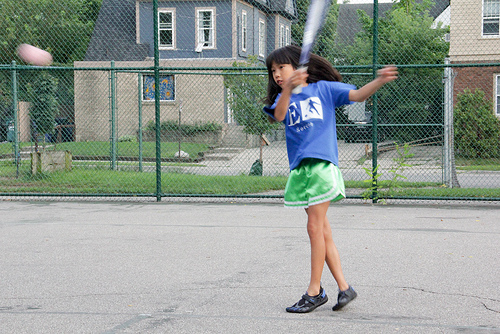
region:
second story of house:
[91, 1, 291, 61]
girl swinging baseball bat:
[260, 1, 398, 313]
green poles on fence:
[2, 2, 496, 200]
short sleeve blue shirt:
[268, 82, 357, 169]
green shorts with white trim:
[283, 160, 346, 211]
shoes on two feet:
[285, 286, 355, 317]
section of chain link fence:
[375, 67, 495, 192]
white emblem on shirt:
[285, 95, 325, 131]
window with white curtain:
[192, 6, 218, 55]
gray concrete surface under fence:
[1, 197, 496, 332]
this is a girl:
[260, 40, 426, 327]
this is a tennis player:
[239, 123, 358, 325]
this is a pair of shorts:
[265, 110, 324, 242]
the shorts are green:
[281, 128, 378, 210]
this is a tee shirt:
[269, 112, 334, 123]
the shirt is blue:
[225, 44, 368, 161]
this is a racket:
[258, 51, 348, 78]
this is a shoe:
[271, 192, 368, 327]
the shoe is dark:
[276, 229, 333, 324]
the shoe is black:
[265, 271, 310, 323]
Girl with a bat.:
[245, 20, 382, 332]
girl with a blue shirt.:
[211, 14, 410, 331]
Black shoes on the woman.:
[267, 279, 454, 331]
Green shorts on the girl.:
[265, 144, 370, 217]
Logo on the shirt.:
[247, 79, 372, 146]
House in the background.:
[53, 12, 348, 255]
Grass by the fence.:
[48, 87, 295, 258]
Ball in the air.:
[20, 21, 61, 102]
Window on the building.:
[133, 9, 238, 56]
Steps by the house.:
[143, 61, 258, 183]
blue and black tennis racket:
[308, 0, 326, 75]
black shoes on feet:
[289, 280, 365, 317]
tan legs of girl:
[302, 204, 345, 288]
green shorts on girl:
[275, 161, 345, 216]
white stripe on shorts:
[316, 171, 350, 201]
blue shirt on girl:
[265, 80, 362, 165]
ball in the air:
[13, 37, 53, 99]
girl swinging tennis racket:
[250, 0, 398, 331]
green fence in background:
[77, 13, 231, 185]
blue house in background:
[136, 5, 231, 55]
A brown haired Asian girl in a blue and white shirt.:
[266, 43, 398, 313]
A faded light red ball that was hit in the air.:
[15, 42, 53, 68]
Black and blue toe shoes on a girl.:
[285, 285, 358, 312]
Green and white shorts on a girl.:
[282, 160, 346, 207]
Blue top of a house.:
[133, 2, 294, 58]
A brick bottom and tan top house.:
[446, 1, 498, 145]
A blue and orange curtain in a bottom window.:
[140, 70, 175, 100]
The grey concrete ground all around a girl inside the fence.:
[4, 199, 499, 331]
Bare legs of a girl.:
[300, 200, 349, 295]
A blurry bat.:
[289, 0, 326, 92]